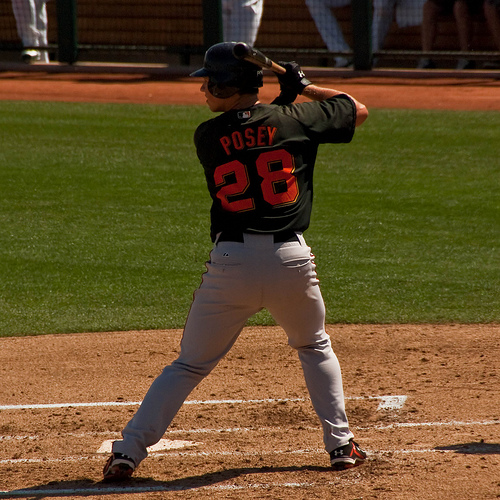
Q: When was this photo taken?
A: During the day.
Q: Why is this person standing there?
A: To bat.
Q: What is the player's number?
A: 28.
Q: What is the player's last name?
A: Posey.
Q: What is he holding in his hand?
A: A baseball bat.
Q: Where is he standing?
A: In the batter's box.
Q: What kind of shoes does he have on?
A: Cleats.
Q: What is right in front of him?
A: Home Plate.